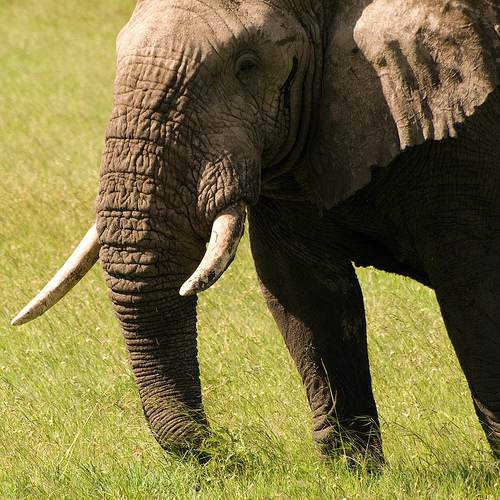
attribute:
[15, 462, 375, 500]
grass — green, long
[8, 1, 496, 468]
elephant — standing, gray, brown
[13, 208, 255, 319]
ivory — white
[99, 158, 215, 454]
nose — long, large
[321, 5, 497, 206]
ears — big, floppy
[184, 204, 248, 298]
tusk — pointy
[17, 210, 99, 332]
tusk — pointy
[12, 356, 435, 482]
field — green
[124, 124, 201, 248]
skin — wrinkly